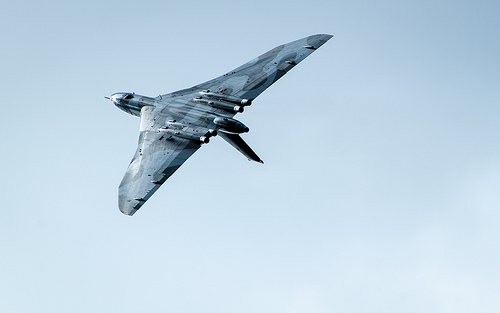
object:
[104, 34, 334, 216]
airplane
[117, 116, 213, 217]
wing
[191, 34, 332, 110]
wing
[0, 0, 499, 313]
background